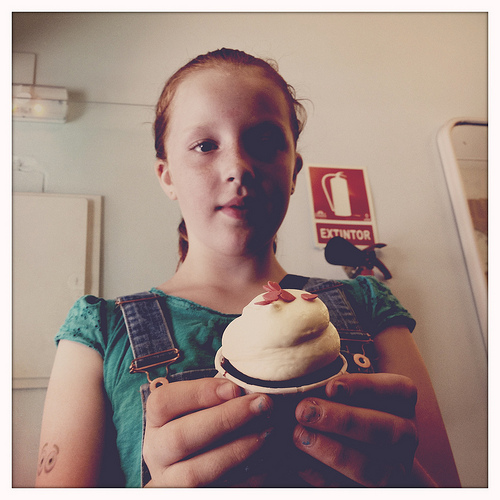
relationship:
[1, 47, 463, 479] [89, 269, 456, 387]
girl wearing a shirt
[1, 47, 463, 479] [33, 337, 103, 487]
girl on girls arm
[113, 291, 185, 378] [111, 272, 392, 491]
strap of overalls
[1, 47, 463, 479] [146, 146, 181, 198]
girl of a ear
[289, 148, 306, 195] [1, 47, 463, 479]
ear of a girl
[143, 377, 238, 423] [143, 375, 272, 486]
finger of a hand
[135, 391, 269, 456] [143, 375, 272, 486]
finger of a hand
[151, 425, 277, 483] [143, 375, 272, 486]
finger of a hand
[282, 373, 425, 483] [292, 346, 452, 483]
fingers of hand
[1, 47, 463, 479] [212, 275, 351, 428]
girl holding cupcake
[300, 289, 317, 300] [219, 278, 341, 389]
chip on top of cake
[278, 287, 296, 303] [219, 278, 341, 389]
chip on top of cake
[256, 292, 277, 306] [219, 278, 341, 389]
chip on top of cake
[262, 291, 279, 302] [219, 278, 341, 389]
decoration on top of cake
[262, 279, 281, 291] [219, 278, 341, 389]
chip on top of cake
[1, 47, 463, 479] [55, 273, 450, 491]
girl wearing shirt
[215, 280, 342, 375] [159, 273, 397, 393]
frosting on cupcake.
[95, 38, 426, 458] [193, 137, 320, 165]
girl has dark eyes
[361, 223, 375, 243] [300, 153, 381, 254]
white letter on sign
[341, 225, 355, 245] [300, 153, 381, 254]
white letter on sign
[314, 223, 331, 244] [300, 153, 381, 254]
white letter on sign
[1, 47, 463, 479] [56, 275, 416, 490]
girl wears shirt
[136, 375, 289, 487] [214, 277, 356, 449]
hand holding cupcake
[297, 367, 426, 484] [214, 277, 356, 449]
hand holding cupcake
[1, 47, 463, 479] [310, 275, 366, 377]
girl wearing overalls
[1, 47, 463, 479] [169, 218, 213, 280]
girl in ponytail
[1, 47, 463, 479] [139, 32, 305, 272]
girl has hair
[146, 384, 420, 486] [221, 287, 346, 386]
two hands holding cupcake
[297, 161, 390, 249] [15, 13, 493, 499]
sign on wall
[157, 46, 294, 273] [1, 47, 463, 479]
head of girl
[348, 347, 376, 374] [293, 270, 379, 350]
button on strap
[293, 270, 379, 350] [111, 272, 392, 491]
strap of overalls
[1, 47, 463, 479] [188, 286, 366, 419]
girl holding cupcake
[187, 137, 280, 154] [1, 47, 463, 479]
dark eyes of girl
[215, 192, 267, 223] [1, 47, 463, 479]
lips of girl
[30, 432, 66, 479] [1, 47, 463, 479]
tattoo on girl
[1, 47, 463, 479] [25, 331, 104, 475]
girl has arm